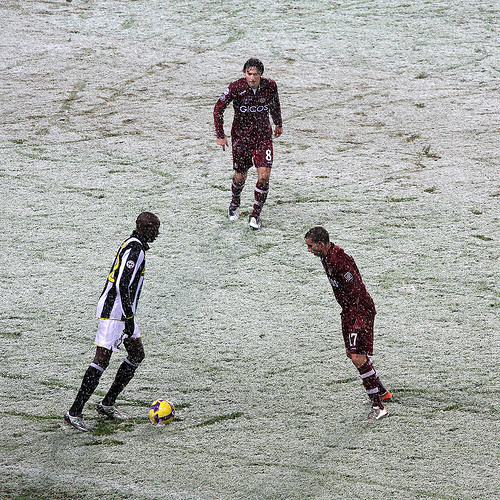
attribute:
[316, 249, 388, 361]
uniform — red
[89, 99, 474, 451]
field — flooded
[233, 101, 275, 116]
letters — white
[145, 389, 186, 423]
ball — purple , yellow , soccer 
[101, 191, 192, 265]
head — bald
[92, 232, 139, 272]
print — yellow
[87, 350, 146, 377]
knee socks — black, white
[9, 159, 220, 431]
man — black 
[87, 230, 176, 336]
uniform — white 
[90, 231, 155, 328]
jersey — black, white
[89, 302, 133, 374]
shorts — white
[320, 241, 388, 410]
uniform — maroon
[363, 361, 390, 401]
sock — maroon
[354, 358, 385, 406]
sock — maroon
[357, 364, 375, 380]
stripe — white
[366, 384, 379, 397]
stripe — white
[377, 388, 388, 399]
stripe — white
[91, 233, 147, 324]
shirt — striped